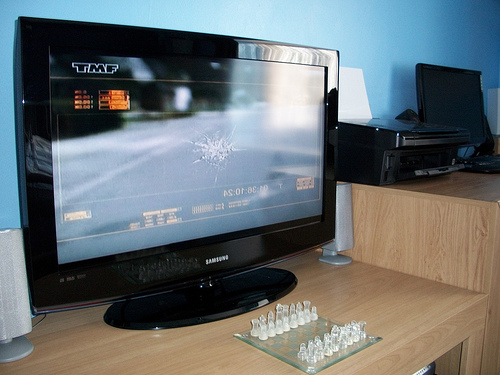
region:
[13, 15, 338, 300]
Large flat screen computer monitor.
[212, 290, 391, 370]
Clear and frosted glass chess set.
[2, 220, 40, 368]
Small white computer speaker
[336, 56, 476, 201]
Black Hewlett Packard computer printer.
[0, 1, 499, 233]
Light blue walls of an office.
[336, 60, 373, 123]
White paper for a computer printer.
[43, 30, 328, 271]
Video game displayed on a computer monitor.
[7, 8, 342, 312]
Big Samsung monitor for a computer.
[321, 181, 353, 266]
Speaker for a computer workstation.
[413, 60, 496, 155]
Small black computer monitor.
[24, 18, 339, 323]
large black computer monitor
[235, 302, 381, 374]
a chess set in front of the monitor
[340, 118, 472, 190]
a black printer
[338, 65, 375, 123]
paper being fed into the printer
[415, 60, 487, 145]
black computer screen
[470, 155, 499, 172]
black computer keyboard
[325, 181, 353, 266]
gray speaker on the right of the monitor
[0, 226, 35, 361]
gray speaker on the left of the monitor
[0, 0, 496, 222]
blue wall behind the desk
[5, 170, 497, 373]
light colored desk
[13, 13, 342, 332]
Black LED TV on the table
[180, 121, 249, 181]
Cracked glass on the TV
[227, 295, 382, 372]
Glass chess infront of the TV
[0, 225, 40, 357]
Left hand speakers next to the TV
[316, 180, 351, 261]
Right hand speakers next to the TV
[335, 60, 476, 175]
Black printer near the TV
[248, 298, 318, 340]
Chess pieces on the glass chess board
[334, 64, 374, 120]
White paper in the printer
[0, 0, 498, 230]
Blue wall in the back ground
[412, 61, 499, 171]
Computer monitor next to the printer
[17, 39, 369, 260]
black tv on desk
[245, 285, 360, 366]
glass chess set on desk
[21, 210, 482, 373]
wooden desk on bottom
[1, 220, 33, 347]
gray speaker on desk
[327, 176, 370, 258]
gray speaker on desk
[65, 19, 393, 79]
blue wall behind tv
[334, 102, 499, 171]
black stereo system on right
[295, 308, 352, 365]
glass chess pieces on square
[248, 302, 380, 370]
square glass chess board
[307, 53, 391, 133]
white paper against wall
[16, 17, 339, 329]
flat screen tv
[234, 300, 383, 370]
glass chess set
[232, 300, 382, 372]
chess set ready for a match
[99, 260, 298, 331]
black tv stand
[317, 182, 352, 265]
silver right speaker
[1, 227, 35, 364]
silver left speaker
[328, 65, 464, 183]
black printer on wooden desk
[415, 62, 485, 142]
computer monitor on wooden desk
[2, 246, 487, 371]
wooden table with tv on it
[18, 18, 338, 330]
tv on a wooden table